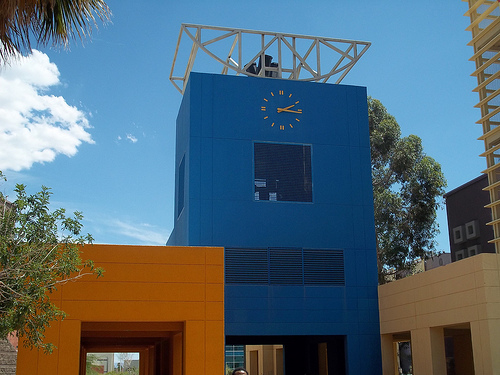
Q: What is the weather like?
A: It is clear.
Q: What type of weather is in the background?
A: It is clear.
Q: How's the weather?
A: It is clear.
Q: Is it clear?
A: Yes, it is clear.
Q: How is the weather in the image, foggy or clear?
A: It is clear.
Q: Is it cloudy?
A: No, it is clear.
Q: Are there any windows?
A: Yes, there is a window.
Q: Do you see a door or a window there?
A: Yes, there is a window.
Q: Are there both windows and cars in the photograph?
A: No, there is a window but no cars.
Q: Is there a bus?
A: No, there are no buses.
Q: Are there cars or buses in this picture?
A: No, there are no buses or cars.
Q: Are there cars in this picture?
A: No, there are no cars.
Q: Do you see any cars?
A: No, there are no cars.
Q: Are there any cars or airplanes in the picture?
A: No, there are no cars or airplanes.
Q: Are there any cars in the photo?
A: No, there are no cars.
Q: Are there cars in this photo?
A: No, there are no cars.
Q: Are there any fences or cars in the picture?
A: No, there are no cars or fences.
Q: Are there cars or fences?
A: No, there are no cars or fences.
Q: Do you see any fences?
A: No, there are no fences.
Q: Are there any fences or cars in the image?
A: No, there are no fences or cars.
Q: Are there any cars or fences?
A: No, there are no fences or cars.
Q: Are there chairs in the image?
A: No, there are no chairs.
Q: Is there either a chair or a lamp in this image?
A: No, there are no chairs or lamps.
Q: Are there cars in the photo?
A: No, there are no cars.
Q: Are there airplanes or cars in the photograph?
A: No, there are no cars or airplanes.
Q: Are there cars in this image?
A: No, there are no cars.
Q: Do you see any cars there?
A: No, there are no cars.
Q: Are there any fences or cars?
A: No, there are no cars or fences.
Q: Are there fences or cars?
A: No, there are no cars or fences.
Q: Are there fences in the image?
A: No, there are no fences.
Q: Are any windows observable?
A: Yes, there is a window.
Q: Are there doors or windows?
A: Yes, there is a window.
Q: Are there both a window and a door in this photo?
A: No, there is a window but no doors.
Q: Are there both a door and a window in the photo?
A: No, there is a window but no doors.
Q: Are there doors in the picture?
A: No, there are no doors.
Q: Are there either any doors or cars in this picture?
A: No, there are no doors or cars.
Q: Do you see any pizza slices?
A: No, there are no pizza slices.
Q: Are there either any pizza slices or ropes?
A: No, there are no pizza slices or ropes.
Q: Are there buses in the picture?
A: No, there are no buses.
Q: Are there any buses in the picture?
A: No, there are no buses.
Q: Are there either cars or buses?
A: No, there are no buses or cars.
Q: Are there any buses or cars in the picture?
A: No, there are no buses or cars.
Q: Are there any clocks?
A: Yes, there is a clock.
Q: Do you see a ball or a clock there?
A: Yes, there is a clock.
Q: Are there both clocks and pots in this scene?
A: No, there is a clock but no pots.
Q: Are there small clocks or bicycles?
A: Yes, there is a small clock.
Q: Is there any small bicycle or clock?
A: Yes, there is a small clock.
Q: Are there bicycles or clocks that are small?
A: Yes, the clock is small.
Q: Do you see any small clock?
A: Yes, there is a small clock.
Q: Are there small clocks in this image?
A: Yes, there is a small clock.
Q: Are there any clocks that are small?
A: Yes, there is a clock that is small.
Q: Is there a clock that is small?
A: Yes, there is a clock that is small.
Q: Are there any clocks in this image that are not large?
A: Yes, there is a small clock.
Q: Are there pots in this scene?
A: No, there are no pots.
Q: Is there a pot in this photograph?
A: No, there are no pots.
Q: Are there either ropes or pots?
A: No, there are no pots or ropes.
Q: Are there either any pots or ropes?
A: No, there are no pots or ropes.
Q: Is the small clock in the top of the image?
A: Yes, the clock is in the top of the image.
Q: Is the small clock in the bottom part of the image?
A: No, the clock is in the top of the image.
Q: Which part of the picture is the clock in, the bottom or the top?
A: The clock is in the top of the image.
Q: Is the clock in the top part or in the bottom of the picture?
A: The clock is in the top of the image.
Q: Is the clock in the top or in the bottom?
A: The clock is in the top of the image.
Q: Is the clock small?
A: Yes, the clock is small.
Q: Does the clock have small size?
A: Yes, the clock is small.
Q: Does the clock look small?
A: Yes, the clock is small.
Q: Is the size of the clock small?
A: Yes, the clock is small.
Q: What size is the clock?
A: The clock is small.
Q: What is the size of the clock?
A: The clock is small.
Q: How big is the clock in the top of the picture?
A: The clock is small.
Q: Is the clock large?
A: No, the clock is small.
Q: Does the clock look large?
A: No, the clock is small.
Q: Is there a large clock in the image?
A: No, there is a clock but it is small.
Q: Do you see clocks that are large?
A: No, there is a clock but it is small.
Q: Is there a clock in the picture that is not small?
A: No, there is a clock but it is small.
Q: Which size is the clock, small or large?
A: The clock is small.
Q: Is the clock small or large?
A: The clock is small.